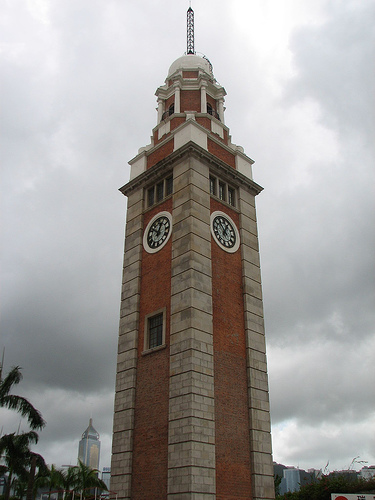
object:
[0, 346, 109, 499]
tree branches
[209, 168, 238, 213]
window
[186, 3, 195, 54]
lightning rod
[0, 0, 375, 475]
cloudy sky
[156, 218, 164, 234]
black hands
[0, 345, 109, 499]
palm trees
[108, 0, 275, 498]
buildings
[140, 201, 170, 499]
wall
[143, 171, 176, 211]
window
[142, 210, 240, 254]
clock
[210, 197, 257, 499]
wall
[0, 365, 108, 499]
tree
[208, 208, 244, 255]
clock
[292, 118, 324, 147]
white clouds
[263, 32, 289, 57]
blue sky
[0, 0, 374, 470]
cloud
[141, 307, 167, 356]
window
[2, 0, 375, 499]
background